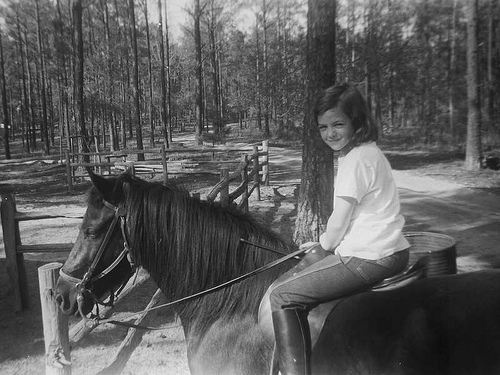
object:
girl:
[266, 85, 412, 374]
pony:
[44, 157, 499, 374]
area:
[2, 1, 500, 207]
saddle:
[269, 242, 413, 373]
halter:
[50, 189, 304, 325]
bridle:
[48, 204, 267, 323]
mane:
[125, 184, 258, 322]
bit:
[73, 290, 98, 326]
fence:
[1, 137, 273, 375]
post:
[260, 138, 271, 188]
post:
[250, 144, 265, 202]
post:
[238, 150, 252, 215]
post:
[219, 166, 232, 205]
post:
[36, 257, 78, 373]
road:
[176, 97, 499, 287]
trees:
[457, 1, 483, 177]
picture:
[1, 1, 499, 375]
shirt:
[316, 141, 413, 262]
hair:
[312, 82, 374, 140]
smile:
[326, 137, 344, 143]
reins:
[247, 236, 478, 374]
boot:
[271, 306, 319, 375]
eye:
[84, 227, 100, 238]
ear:
[85, 166, 120, 198]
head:
[47, 161, 140, 319]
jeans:
[266, 236, 422, 311]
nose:
[327, 128, 339, 139]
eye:
[319, 125, 329, 130]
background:
[1, 1, 500, 258]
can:
[401, 228, 456, 277]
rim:
[401, 228, 457, 254]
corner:
[209, 136, 275, 211]